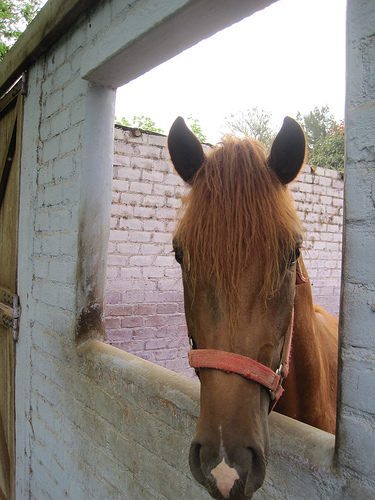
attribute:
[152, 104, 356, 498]
horse — brown, looking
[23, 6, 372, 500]
wall — white, brick, old, dirty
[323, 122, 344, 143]
flowers — red, growing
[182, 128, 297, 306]
hair — brown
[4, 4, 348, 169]
sky — bright, sunny, white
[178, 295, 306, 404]
bridle — red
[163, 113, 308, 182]
ears — sticking up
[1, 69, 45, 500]
door — wooden, open, brown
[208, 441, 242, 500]
spot — white